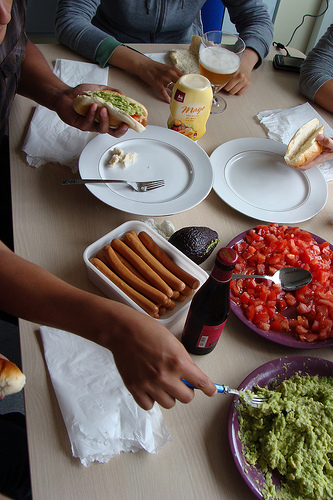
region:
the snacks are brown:
[120, 254, 172, 289]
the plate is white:
[212, 147, 283, 195]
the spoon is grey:
[281, 273, 307, 282]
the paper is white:
[79, 347, 104, 464]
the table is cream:
[135, 454, 215, 499]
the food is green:
[267, 379, 332, 499]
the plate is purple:
[230, 414, 238, 462]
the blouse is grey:
[307, 46, 332, 79]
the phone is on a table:
[274, 55, 298, 70]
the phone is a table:
[272, 55, 300, 70]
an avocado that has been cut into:
[169, 224, 218, 263]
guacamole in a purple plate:
[229, 355, 331, 499]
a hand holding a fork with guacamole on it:
[106, 312, 273, 420]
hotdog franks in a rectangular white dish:
[81, 218, 206, 322]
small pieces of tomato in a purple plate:
[221, 219, 327, 344]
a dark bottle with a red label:
[177, 245, 233, 350]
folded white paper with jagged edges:
[36, 323, 166, 461]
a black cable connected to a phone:
[270, 0, 325, 71]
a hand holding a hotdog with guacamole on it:
[58, 82, 145, 135]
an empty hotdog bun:
[281, 117, 325, 166]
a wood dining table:
[8, 43, 332, 499]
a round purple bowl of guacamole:
[227, 355, 331, 499]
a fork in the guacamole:
[181, 378, 268, 408]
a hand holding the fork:
[0, 239, 217, 409]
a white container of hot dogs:
[82, 219, 208, 329]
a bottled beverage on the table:
[180, 247, 237, 355]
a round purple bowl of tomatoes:
[224, 224, 332, 349]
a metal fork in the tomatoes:
[205, 266, 311, 290]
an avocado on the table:
[167, 226, 219, 265]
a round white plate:
[209, 137, 327, 223]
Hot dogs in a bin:
[98, 231, 195, 322]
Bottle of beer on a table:
[202, 248, 230, 363]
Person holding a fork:
[161, 346, 272, 430]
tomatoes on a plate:
[245, 232, 321, 325]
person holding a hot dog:
[76, 82, 153, 137]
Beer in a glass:
[196, 30, 239, 95]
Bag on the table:
[34, 345, 170, 463]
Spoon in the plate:
[247, 248, 309, 300]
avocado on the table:
[178, 228, 214, 264]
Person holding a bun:
[288, 112, 330, 173]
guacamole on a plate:
[236, 363, 331, 498]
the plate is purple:
[225, 346, 330, 498]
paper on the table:
[36, 309, 175, 472]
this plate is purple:
[213, 216, 330, 348]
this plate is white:
[208, 127, 322, 233]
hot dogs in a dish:
[95, 225, 203, 311]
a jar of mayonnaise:
[166, 72, 214, 141]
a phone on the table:
[271, 46, 308, 75]